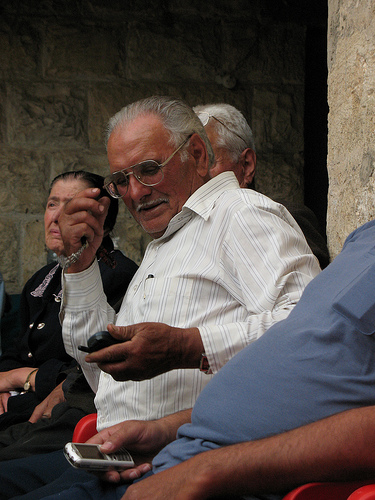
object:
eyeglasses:
[102, 130, 194, 200]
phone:
[75, 327, 119, 356]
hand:
[80, 309, 185, 387]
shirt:
[59, 169, 323, 432]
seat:
[70, 400, 102, 452]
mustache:
[132, 195, 166, 212]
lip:
[140, 206, 162, 221]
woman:
[0, 151, 139, 415]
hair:
[98, 90, 217, 166]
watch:
[22, 374, 36, 394]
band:
[26, 369, 38, 382]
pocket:
[140, 270, 194, 337]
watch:
[52, 238, 94, 272]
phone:
[61, 435, 137, 476]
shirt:
[0, 242, 139, 426]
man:
[0, 85, 327, 500]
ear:
[185, 132, 211, 181]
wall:
[0, 0, 322, 296]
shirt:
[153, 222, 374, 479]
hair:
[46, 168, 120, 239]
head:
[186, 86, 261, 193]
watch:
[198, 346, 211, 376]